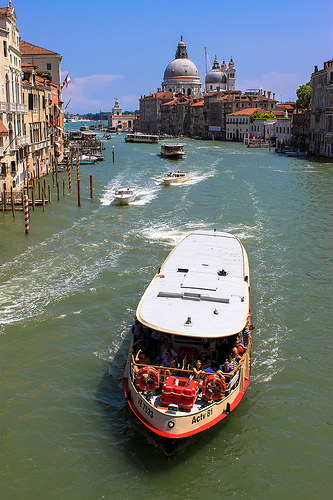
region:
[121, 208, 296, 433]
boat on the water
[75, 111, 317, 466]
boats on a canal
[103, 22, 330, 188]
buildings along the water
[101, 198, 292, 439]
a passenger ferry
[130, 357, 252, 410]
life preservers on a boat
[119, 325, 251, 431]
people riding on a boat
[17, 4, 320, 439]
a warm day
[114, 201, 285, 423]
the top of the boat is grey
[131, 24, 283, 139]
a building with two domes on top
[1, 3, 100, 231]
waterfront buildings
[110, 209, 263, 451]
passenger ferry on river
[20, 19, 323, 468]
picture of Venice, Italy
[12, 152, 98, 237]
poles in water to anchor boats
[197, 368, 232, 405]
orange life rings on boat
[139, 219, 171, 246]
white foam of water caused by moving boat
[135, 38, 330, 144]
buildings along river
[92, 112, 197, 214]
many boats on the river with passengers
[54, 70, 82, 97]
flag hanging from building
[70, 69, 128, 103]
wispy white clouds in sky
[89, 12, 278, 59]
clear blue skies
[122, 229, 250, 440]
tourist boat filled with passengers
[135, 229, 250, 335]
white roof of boat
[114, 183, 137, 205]
first small boat behind tour boat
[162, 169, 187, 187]
second small boat behind tour boat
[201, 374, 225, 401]
floatation devices on left side of boat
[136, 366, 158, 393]
floatation devices on right side of boat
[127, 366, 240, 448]
front of the tour boat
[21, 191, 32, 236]
red and white pole in water on left side of picture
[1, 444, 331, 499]
murky water in front of boat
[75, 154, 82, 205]
tall red and yellow pole behind boat on left side of picture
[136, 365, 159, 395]
Left circle life saver on the boat.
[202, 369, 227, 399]
Right side circle life saver.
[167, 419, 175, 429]
Head light on the boat.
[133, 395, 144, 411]
Two letters on the left side of the boat.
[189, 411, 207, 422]
Four letters on the right side of the boat.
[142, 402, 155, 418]
Numbers on the left side of the boat.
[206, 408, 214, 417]
Numbers on the right side of the boat.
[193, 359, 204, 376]
Girl with sunglasses on standing next to the right side circle life saver.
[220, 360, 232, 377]
Man in the blue t-shirt standing next to the right circle life saver.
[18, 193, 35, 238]
Short red and white striped pole to the left of the boat.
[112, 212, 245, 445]
a tour boat on the river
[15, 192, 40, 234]
a striped pole in the water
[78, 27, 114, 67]
a clear blue sky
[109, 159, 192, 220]
boats racing down the river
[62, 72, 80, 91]
a flag on a building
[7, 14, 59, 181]
apartment buildings next to the river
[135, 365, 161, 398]
a red inner tube on the boat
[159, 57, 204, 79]
the dome roof on a building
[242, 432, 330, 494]
dark green river water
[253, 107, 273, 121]
plants growing on the roof of building